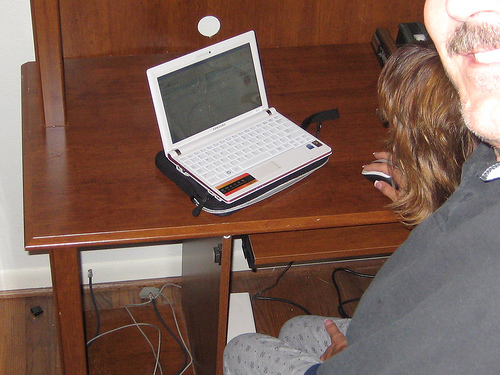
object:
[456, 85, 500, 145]
mans chin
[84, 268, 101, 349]
cords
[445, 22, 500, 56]
mustache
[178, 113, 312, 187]
keyboard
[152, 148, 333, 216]
laptop case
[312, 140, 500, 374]
black shirt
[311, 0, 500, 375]
man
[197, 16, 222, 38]
hole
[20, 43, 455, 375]
desk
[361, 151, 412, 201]
hand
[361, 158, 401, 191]
mouse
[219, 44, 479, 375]
woman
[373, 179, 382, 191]
fingernail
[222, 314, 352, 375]
pajama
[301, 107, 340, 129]
strap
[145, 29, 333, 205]
laptop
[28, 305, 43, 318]
piece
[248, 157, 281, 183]
mouse pad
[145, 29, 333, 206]
computer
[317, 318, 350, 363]
hands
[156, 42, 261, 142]
screen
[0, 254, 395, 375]
floor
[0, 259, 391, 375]
ground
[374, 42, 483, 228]
hair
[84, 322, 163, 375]
wire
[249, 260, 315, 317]
cords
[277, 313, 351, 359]
legs.